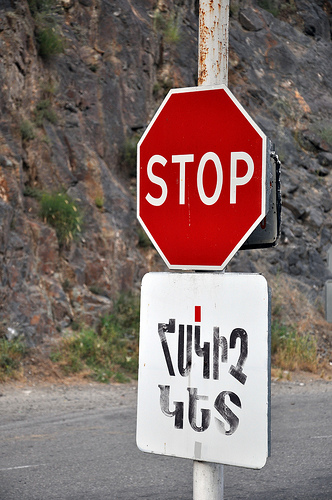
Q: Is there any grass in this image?
A: Yes, there is grass.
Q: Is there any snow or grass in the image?
A: Yes, there is grass.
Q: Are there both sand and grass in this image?
A: No, there is grass but no sand.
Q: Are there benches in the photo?
A: No, there are no benches.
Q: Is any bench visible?
A: No, there are no benches.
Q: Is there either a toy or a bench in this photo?
A: No, there are no benches or toys.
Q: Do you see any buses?
A: No, there are no buses.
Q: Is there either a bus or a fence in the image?
A: No, there are no buses or fences.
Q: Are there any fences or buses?
A: No, there are no buses or fences.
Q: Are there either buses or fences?
A: No, there are no buses or fences.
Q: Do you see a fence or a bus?
A: No, there are no buses or fences.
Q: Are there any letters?
A: Yes, there are letters.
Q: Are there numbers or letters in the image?
A: Yes, there are letters.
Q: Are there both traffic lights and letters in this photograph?
A: No, there are letters but no traffic lights.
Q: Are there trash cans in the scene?
A: No, there are no trash cans.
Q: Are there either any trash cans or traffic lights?
A: No, there are no trash cans or traffic lights.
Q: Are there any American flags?
A: No, there are no American flags.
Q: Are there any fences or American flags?
A: No, there are no American flags or fences.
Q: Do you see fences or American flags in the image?
A: No, there are no American flags or fences.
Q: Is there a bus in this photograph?
A: No, there are no buses.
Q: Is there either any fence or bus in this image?
A: No, there are no buses or fences.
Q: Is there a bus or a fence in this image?
A: No, there are no buses or fences.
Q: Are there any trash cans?
A: No, there are no trash cans.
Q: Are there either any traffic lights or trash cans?
A: No, there are no trash cans or traffic lights.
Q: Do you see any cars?
A: No, there are no cars.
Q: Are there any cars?
A: No, there are no cars.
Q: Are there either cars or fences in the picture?
A: No, there are no cars or fences.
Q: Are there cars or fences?
A: No, there are no cars or fences.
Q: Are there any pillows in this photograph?
A: No, there are no pillows.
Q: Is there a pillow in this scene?
A: No, there are no pillows.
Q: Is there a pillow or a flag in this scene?
A: No, there are no pillows or flags.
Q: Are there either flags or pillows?
A: No, there are no pillows or flags.